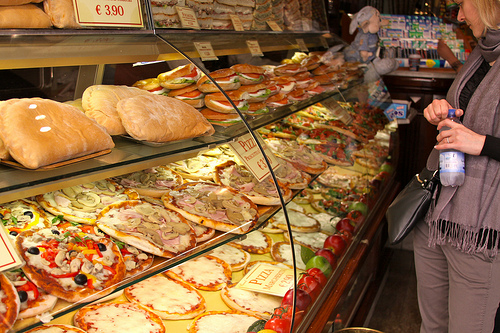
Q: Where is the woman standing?
A: Deli counter.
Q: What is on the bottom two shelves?
A: Pizza.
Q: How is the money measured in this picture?
A: Euros.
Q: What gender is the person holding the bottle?
A: Female.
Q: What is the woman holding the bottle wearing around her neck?
A: Scarf.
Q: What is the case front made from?
A: Glass.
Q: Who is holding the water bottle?
A: Woman.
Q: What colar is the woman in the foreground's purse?
A: Black.